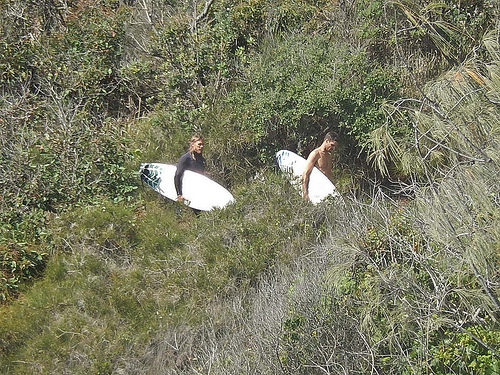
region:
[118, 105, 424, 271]
two men in the bushes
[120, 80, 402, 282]
the men are holding surfboards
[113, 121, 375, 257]
the surfboards are white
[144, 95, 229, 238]
the man is wearing wetsuits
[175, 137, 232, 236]
the wet suit is black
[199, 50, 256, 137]
the grasses are green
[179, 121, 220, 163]
the man's hair is long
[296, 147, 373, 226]
the man is not wearing shirt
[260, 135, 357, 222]
the surfboard is white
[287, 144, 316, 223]
the arm is long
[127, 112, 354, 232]
two men walking with surfboards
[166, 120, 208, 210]
man is wearing a wetsuit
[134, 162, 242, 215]
surfboard is white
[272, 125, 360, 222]
man holding a surfboard is shirtless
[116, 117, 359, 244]
both men are facing right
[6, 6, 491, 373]
men are walking through dense undergrowth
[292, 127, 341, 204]
man without a shirt has dark short hair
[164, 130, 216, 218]
surfer in a wetsuit has blond hair and a beard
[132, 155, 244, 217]
white surfboard has a pattern on the end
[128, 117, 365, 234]
two men with surfboards under their right arms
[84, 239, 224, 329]
the grass is green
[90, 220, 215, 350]
the grass is tall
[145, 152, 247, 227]
the board is white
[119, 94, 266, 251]
the man is holding a board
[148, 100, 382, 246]
there are two men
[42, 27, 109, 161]
the trees are green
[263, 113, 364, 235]
the man has no shirt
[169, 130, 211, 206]
the shirt is black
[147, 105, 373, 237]
the men are walking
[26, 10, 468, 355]
there are lots of plants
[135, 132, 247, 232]
surfboarder is holding his surfboard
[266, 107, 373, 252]
surfboarder is holding his surfboard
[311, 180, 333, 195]
part of a swimming board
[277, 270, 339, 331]
part of some dry grass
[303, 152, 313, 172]
right bicep of a man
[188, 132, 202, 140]
hair of a man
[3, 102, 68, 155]
part of some branches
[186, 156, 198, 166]
part of a swimming costume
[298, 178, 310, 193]
right arm of a man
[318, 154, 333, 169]
chest of a man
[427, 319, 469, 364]
part of some green plants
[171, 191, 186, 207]
right hand of a man